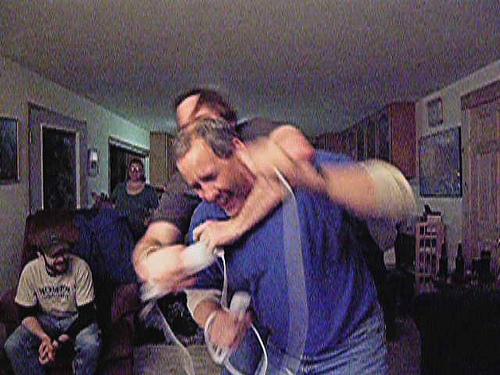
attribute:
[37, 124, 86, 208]
doorway —  cracked open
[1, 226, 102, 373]
man —  down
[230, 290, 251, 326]
remote — white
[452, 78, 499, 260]
door —  closed ,  tan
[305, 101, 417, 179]
cupboards —  brown ,  upper,  kitchen's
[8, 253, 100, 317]
t-shirt — tan, short-sleeve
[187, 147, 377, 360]
blue shirt — short-sleeve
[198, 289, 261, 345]
remote — white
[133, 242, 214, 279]
remote — white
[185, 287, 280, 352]
remote — white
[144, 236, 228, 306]
remote — white